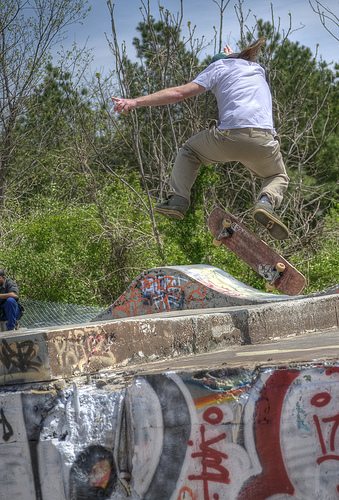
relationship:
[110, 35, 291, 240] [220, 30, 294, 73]
man has brown hair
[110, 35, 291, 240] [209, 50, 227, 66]
man has cap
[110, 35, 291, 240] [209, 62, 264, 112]
man has grey shirt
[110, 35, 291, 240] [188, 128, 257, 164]
man has tan pants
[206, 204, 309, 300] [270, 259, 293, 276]
skateboard has tan wheels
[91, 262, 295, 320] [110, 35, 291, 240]
ramp behind man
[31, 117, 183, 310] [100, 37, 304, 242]
green trees behind skater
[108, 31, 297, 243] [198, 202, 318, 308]
man on skateboard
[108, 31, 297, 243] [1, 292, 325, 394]
man jumping off ground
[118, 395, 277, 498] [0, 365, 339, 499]
graffitti on graffiti on wall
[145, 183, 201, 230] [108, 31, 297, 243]
shoe of man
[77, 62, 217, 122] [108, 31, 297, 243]
arm of man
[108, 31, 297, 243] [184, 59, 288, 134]
man wearing purple shirt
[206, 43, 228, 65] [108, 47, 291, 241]
cap on man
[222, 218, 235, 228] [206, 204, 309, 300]
wheel on skateboard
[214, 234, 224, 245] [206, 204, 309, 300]
wheel on skateboard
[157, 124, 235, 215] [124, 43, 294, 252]
leg on man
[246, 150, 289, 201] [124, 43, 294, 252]
he leg of a man on man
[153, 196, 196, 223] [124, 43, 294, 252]
foot on man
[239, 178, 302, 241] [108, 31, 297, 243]
foot on man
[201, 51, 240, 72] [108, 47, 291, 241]
head on man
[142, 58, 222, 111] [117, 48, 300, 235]
arm on man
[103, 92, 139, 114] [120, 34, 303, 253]
hand on man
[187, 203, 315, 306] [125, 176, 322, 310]
skateboard flips in air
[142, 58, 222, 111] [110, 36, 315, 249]
arm of person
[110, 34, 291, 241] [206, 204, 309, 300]
jumping off a skateboard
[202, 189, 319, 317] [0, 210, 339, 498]
skateboard in mid above above rink.